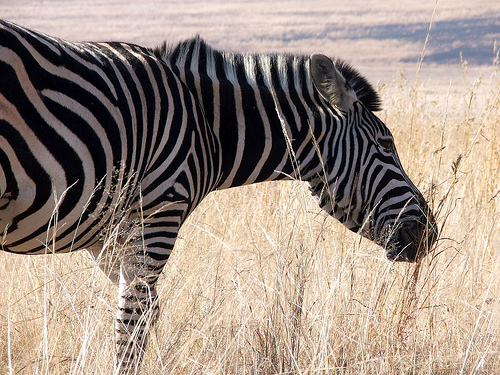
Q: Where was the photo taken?
A: It was taken at the field.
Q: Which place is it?
A: It is a field.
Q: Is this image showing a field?
A: Yes, it is showing a field.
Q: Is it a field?
A: Yes, it is a field.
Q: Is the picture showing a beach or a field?
A: It is showing a field.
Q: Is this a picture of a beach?
A: No, the picture is showing a field.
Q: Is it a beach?
A: No, it is a field.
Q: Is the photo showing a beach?
A: No, the picture is showing a field.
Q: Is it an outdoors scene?
A: Yes, it is outdoors.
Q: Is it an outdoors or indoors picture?
A: It is outdoors.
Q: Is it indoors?
A: No, it is outdoors.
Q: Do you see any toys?
A: No, there are no toys.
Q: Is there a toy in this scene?
A: No, there are no toys.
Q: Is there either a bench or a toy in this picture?
A: No, there are no toys or benches.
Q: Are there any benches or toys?
A: No, there are no toys or benches.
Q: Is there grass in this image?
A: Yes, there is grass.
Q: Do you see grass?
A: Yes, there is grass.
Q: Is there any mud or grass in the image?
A: Yes, there is grass.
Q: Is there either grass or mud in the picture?
A: Yes, there is grass.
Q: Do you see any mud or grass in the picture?
A: Yes, there is grass.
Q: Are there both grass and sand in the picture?
A: No, there is grass but no sand.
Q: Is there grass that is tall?
A: Yes, there is tall grass.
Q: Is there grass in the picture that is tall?
A: Yes, there is grass that is tall.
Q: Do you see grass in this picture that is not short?
A: Yes, there is tall grass.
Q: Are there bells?
A: No, there are no bells.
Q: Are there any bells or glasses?
A: No, there are no bells or glasses.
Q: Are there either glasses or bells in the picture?
A: No, there are no bells or glasses.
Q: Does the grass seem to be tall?
A: Yes, the grass is tall.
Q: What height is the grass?
A: The grass is tall.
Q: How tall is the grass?
A: The grass is tall.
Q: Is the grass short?
A: No, the grass is tall.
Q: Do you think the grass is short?
A: No, the grass is tall.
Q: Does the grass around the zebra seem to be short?
A: No, the grass is tall.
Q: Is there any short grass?
A: No, there is grass but it is tall.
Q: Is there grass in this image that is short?
A: No, there is grass but it is tall.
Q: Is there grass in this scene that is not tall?
A: No, there is grass but it is tall.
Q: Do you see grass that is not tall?
A: No, there is grass but it is tall.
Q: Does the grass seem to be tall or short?
A: The grass is tall.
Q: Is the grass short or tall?
A: The grass is tall.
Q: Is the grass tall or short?
A: The grass is tall.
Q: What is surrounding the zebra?
A: The grass is surrounding the zebra.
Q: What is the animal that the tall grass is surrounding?
A: The animal is a zebra.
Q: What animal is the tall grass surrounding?
A: The grass is surrounding the zebra.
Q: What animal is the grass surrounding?
A: The grass is surrounding the zebra.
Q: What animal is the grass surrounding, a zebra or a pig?
A: The grass is surrounding a zebra.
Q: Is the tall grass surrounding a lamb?
A: No, the grass is surrounding a zebra.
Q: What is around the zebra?
A: The grass is around the zebra.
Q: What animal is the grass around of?
A: The grass is around the zebra.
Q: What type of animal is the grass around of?
A: The grass is around the zebra.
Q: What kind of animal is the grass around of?
A: The grass is around the zebra.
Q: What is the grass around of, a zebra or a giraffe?
A: The grass is around a zebra.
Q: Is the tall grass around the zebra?
A: Yes, the grass is around the zebra.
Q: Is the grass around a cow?
A: No, the grass is around the zebra.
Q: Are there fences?
A: No, there are no fences.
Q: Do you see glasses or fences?
A: No, there are no fences or glasses.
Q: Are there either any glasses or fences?
A: No, there are no fences or glasses.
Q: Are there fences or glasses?
A: No, there are no fences or glasses.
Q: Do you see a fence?
A: No, there are no fences.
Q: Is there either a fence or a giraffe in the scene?
A: No, there are no fences or giraffes.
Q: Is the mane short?
A: Yes, the mane is short.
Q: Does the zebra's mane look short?
A: Yes, the mane is short.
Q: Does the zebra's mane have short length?
A: Yes, the mane is short.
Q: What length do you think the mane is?
A: The mane is short.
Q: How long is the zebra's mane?
A: The mane is short.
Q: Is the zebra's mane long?
A: No, the mane is short.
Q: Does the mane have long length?
A: No, the mane is short.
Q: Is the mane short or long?
A: The mane is short.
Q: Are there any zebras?
A: Yes, there is a zebra.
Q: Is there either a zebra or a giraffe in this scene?
A: Yes, there is a zebra.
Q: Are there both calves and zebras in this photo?
A: No, there is a zebra but no calves.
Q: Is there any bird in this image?
A: No, there are no birds.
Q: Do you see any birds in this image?
A: No, there are no birds.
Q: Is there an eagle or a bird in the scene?
A: No, there are no birds or eagles.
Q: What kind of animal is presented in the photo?
A: The animal is a zebra.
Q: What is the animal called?
A: The animal is a zebra.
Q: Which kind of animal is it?
A: The animal is a zebra.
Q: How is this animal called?
A: This is a zebra.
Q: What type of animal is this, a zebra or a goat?
A: This is a zebra.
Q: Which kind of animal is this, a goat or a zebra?
A: This is a zebra.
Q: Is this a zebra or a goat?
A: This is a zebra.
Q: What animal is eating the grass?
A: The zebra is eating the grass.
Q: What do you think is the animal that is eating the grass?
A: The animal is a zebra.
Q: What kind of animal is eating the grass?
A: The animal is a zebra.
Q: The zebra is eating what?
A: The zebra is eating grass.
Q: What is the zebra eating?
A: The zebra is eating grass.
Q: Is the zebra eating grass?
A: Yes, the zebra is eating grass.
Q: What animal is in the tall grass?
A: The zebra is in the grass.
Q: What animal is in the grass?
A: The zebra is in the grass.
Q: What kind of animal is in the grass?
A: The animal is a zebra.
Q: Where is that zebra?
A: The zebra is in the grass.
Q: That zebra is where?
A: The zebra is in the grass.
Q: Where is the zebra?
A: The zebra is in the grass.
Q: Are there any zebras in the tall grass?
A: Yes, there is a zebra in the grass.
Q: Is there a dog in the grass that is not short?
A: No, there is a zebra in the grass.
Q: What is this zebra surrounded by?
A: The zebra is surrounded by the grass.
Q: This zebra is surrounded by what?
A: The zebra is surrounded by the grass.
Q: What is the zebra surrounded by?
A: The zebra is surrounded by the grass.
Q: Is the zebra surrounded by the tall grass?
A: Yes, the zebra is surrounded by the grass.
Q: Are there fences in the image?
A: No, there are no fences.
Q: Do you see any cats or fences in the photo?
A: No, there are no fences or cats.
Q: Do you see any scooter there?
A: No, there are no scooters.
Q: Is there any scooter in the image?
A: No, there are no scooters.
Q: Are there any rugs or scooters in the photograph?
A: No, there are no scooters or rugs.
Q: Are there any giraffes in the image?
A: No, there are no giraffes.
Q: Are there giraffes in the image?
A: No, there are no giraffes.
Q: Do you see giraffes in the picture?
A: No, there are no giraffes.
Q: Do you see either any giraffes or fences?
A: No, there are no giraffes or fences.